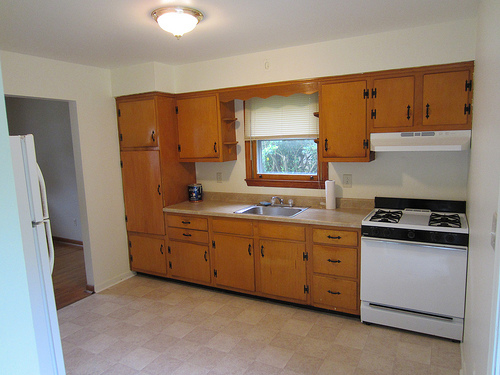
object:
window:
[251, 92, 319, 179]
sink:
[241, 207, 302, 217]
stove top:
[361, 208, 468, 234]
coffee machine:
[187, 183, 203, 202]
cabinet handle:
[151, 131, 155, 142]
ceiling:
[1, 0, 485, 65]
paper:
[325, 180, 336, 210]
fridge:
[7, 133, 68, 375]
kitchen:
[0, 0, 498, 375]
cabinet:
[116, 60, 475, 315]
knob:
[327, 235, 341, 239]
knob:
[204, 251, 208, 261]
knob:
[261, 246, 265, 258]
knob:
[182, 221, 191, 224]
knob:
[183, 234, 192, 237]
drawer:
[312, 228, 358, 247]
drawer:
[312, 274, 358, 310]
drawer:
[128, 234, 167, 274]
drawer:
[120, 151, 166, 236]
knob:
[157, 185, 161, 195]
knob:
[327, 259, 341, 263]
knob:
[327, 290, 341, 295]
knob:
[248, 244, 251, 256]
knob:
[160, 244, 164, 255]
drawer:
[168, 241, 211, 283]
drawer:
[313, 244, 358, 278]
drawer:
[259, 240, 307, 301]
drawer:
[166, 214, 209, 231]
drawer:
[167, 227, 209, 244]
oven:
[359, 208, 470, 342]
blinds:
[244, 92, 319, 141]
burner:
[370, 210, 403, 223]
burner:
[428, 212, 461, 227]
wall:
[0, 54, 107, 93]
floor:
[78, 313, 288, 373]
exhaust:
[369, 130, 472, 152]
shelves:
[224, 140, 238, 154]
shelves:
[223, 118, 237, 130]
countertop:
[164, 198, 373, 228]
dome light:
[151, 7, 203, 42]